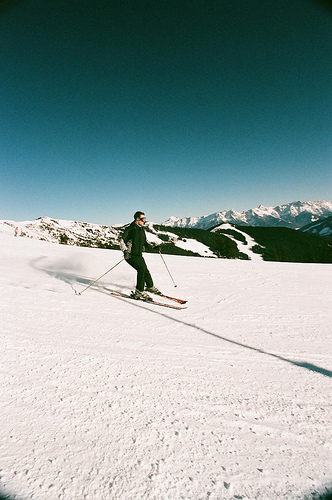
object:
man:
[117, 211, 155, 302]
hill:
[0, 216, 332, 499]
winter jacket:
[120, 220, 159, 259]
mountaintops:
[185, 199, 332, 222]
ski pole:
[78, 241, 178, 296]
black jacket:
[121, 220, 154, 258]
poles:
[154, 241, 178, 287]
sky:
[0, 0, 328, 222]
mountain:
[0, 214, 329, 260]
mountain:
[297, 215, 330, 237]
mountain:
[156, 198, 332, 233]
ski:
[111, 290, 189, 309]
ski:
[133, 285, 188, 304]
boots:
[130, 286, 162, 304]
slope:
[38, 249, 267, 383]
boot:
[145, 285, 163, 296]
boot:
[130, 289, 153, 302]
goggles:
[136, 216, 146, 223]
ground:
[33, 353, 118, 464]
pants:
[123, 254, 153, 292]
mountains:
[151, 188, 331, 263]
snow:
[1, 231, 330, 498]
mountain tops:
[162, 199, 332, 238]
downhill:
[191, 260, 329, 499]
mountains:
[0, 215, 117, 248]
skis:
[111, 279, 189, 310]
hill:
[188, 257, 330, 499]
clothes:
[120, 222, 154, 292]